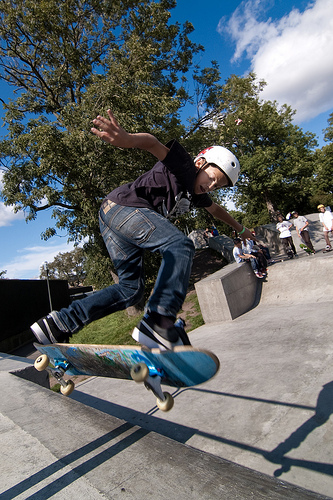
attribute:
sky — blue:
[0, 0, 332, 282]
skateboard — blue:
[31, 342, 218, 411]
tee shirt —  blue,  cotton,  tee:
[104, 145, 213, 219]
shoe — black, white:
[131, 314, 190, 346]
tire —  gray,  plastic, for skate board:
[129, 360, 149, 382]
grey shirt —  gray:
[293, 214, 307, 231]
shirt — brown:
[126, 166, 184, 208]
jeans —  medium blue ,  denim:
[53, 201, 185, 322]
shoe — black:
[129, 306, 193, 356]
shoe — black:
[22, 307, 72, 346]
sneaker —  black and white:
[116, 298, 220, 379]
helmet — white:
[192, 140, 247, 190]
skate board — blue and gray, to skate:
[29, 335, 219, 410]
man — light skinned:
[35, 107, 258, 354]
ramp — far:
[264, 238, 282, 259]